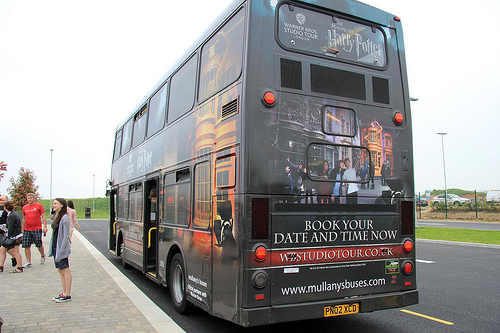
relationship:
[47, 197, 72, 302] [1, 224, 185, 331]
people on sidewalk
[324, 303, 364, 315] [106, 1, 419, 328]
license plate on bus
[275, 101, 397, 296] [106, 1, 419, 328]
ad on bus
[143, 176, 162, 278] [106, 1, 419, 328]
door on bus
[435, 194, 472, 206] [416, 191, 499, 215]
car in parking lot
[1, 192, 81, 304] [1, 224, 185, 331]
people on sidewalk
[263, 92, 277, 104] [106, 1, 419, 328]
light on bus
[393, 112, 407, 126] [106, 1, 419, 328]
light on bus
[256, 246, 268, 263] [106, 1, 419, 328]
light on bus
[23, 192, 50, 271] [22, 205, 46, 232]
man in red shirt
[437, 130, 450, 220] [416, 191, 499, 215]
street light in parking lot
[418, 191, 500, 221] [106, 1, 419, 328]
fence behind bus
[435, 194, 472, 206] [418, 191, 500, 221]
car behind fence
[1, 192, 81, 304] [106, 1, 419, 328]
people near bus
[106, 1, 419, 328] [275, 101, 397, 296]
bus with ad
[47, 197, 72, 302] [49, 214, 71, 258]
people in sweater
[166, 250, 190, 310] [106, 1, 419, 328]
wheel on bus